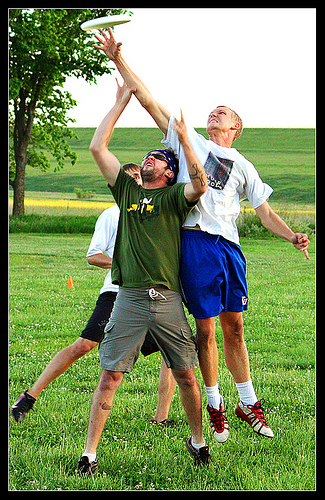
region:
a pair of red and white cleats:
[206, 396, 281, 445]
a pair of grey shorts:
[107, 289, 202, 389]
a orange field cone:
[61, 272, 78, 293]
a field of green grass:
[237, 438, 295, 474]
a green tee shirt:
[111, 169, 192, 284]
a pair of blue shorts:
[186, 227, 253, 314]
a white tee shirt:
[172, 116, 259, 237]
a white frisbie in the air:
[78, 11, 136, 34]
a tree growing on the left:
[14, 49, 79, 229]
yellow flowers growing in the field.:
[36, 188, 101, 214]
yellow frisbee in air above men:
[79, 9, 140, 34]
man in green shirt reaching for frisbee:
[103, 153, 212, 440]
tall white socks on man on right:
[202, 374, 263, 404]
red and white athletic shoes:
[203, 397, 274, 441]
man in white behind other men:
[48, 185, 153, 391]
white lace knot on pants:
[136, 278, 163, 305]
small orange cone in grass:
[53, 269, 80, 287]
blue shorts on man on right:
[174, 237, 256, 324]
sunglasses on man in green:
[130, 139, 178, 175]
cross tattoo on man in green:
[181, 152, 231, 205]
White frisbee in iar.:
[77, 14, 141, 36]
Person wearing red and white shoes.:
[212, 399, 267, 461]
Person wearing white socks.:
[206, 384, 259, 414]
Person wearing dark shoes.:
[81, 456, 113, 491]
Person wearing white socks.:
[86, 448, 104, 466]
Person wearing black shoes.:
[18, 395, 40, 429]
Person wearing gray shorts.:
[109, 305, 154, 350]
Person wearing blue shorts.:
[187, 266, 236, 287]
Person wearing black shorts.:
[82, 302, 101, 334]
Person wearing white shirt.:
[104, 274, 112, 288]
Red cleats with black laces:
[205, 396, 279, 444]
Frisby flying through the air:
[78, 12, 136, 33]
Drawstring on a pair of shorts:
[143, 285, 171, 303]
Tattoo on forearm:
[185, 160, 210, 190]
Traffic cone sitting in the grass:
[65, 270, 74, 296]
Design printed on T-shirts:
[198, 147, 235, 196]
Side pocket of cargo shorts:
[95, 315, 119, 360]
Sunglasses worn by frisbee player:
[140, 151, 166, 163]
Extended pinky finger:
[302, 246, 311, 261]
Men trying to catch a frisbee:
[77, 12, 275, 481]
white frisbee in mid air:
[78, 9, 134, 28]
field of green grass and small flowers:
[14, 221, 324, 494]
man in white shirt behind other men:
[53, 148, 145, 387]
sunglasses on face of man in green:
[135, 144, 162, 166]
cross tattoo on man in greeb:
[182, 144, 208, 191]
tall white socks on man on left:
[204, 370, 274, 409]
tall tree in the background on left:
[24, 0, 101, 216]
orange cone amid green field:
[55, 262, 78, 293]